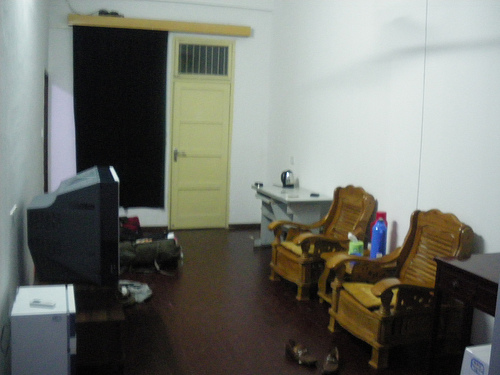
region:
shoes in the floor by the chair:
[283, 336, 342, 373]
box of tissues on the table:
[345, 232, 367, 260]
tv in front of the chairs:
[22, 161, 122, 313]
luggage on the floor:
[114, 215, 182, 275]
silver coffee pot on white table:
[280, 168, 295, 188]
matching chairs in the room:
[266, 183, 473, 366]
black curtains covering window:
[74, 77, 166, 208]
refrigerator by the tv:
[7, 283, 79, 373]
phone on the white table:
[310, 190, 318, 200]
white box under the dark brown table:
[460, 345, 494, 372]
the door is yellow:
[161, 32, 239, 233]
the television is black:
[21, 158, 131, 317]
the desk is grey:
[251, 172, 337, 252]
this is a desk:
[246, 173, 335, 250]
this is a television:
[18, 158, 126, 319]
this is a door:
[155, 33, 243, 234]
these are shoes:
[267, 329, 349, 374]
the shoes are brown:
[281, 333, 342, 374]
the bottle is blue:
[364, 215, 386, 265]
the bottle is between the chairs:
[364, 205, 389, 272]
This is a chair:
[264, 180, 378, 303]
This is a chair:
[325, 202, 487, 374]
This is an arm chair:
[265, 173, 380, 309]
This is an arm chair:
[314, 202, 479, 374]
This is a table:
[430, 240, 499, 371]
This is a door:
[175, 34, 236, 236]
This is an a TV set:
[19, 150, 134, 299]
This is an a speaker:
[4, 278, 83, 373]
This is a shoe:
[280, 333, 316, 370]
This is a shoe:
[314, 343, 349, 373]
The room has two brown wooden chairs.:
[263, 197, 445, 346]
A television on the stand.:
[33, 163, 129, 298]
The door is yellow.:
[175, 54, 257, 254]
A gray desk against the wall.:
[249, 153, 332, 245]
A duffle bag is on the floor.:
[128, 231, 204, 263]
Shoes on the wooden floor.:
[278, 323, 360, 373]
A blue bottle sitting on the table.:
[367, 218, 387, 263]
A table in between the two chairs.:
[288, 189, 415, 332]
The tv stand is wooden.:
[75, 297, 132, 368]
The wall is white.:
[284, 38, 457, 172]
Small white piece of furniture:
[6, 281, 88, 373]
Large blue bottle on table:
[366, 215, 388, 263]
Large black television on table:
[18, 165, 125, 287]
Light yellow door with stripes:
[162, 76, 236, 231]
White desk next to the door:
[235, 167, 324, 270]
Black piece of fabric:
[65, 24, 168, 209]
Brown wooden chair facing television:
[306, 209, 473, 352]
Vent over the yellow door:
[170, 38, 234, 78]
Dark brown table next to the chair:
[431, 244, 498, 373]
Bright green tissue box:
[337, 231, 367, 258]